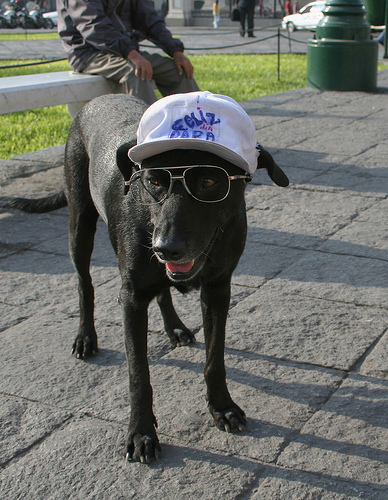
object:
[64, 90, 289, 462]
dog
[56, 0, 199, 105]
man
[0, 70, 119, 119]
bench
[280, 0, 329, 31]
car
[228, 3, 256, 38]
person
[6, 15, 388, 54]
street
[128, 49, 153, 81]
hand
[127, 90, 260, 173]
cap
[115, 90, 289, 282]
head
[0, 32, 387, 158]
grass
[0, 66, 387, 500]
sidewalk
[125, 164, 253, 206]
glasses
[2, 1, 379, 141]
background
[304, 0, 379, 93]
streetlight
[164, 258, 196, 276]
tongue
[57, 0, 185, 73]
jacket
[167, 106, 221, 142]
letters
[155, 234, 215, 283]
mouth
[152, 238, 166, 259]
nose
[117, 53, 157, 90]
knee